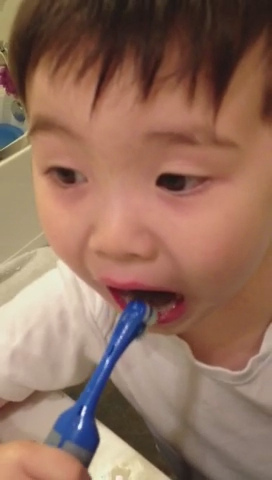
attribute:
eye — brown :
[34, 165, 79, 190]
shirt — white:
[48, 298, 261, 423]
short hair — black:
[4, 0, 270, 136]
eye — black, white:
[154, 170, 210, 196]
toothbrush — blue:
[50, 272, 186, 478]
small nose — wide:
[88, 192, 156, 256]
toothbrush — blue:
[42, 295, 157, 465]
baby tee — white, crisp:
[0, 246, 271, 478]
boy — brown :
[17, 6, 263, 471]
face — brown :
[26, 73, 252, 330]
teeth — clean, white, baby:
[163, 303, 173, 311]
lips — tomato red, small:
[100, 281, 176, 320]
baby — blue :
[0, 11, 249, 434]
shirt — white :
[0, 254, 270, 477]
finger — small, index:
[27, 438, 97, 478]